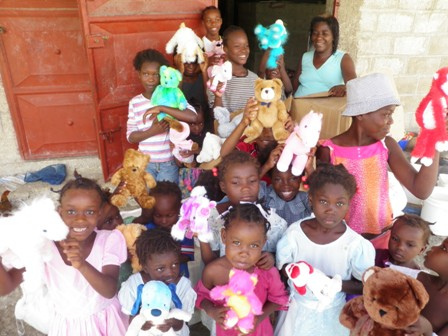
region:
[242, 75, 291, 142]
A light brown teddybear.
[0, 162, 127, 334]
A little girl wearing pink.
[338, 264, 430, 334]
A dark brown teddy bear.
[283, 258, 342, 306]
A red and white stuffed animal.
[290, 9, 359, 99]
A woman smiling wearing a blue shirt.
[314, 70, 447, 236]
A girl wearing a hat.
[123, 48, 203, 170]
A little girl wearing a striped shirt.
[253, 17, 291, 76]
A blue stuffed animal.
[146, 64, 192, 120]
A green stuffed animal.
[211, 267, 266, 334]
A pink stuffed animal.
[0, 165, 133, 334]
young girl in a pink dress holding up a stuffed unicorn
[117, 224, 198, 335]
young girl holding a blue and white stuffed animal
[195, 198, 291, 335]
girl in a dark pink dress holding a pink stuffed animal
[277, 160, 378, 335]
girl in a light blue dress holding a white and red stuffed animal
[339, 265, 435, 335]
stuffed brown teddy bear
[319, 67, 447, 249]
girl looking at her red and white stuffed animal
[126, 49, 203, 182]
girl hugging multicolored stuffed bear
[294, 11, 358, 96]
woman wearing a light blue tank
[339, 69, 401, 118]
hat on a young girl's head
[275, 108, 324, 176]
stuffed pink unicorn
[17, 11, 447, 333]
a group of children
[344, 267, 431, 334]
a brown bear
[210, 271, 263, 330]
a pink and yellow bear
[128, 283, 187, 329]
a blue and white dog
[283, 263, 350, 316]
a red and white dog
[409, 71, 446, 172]
a red and white monkey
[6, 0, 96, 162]
a orange door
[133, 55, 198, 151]
a girl holding a green bear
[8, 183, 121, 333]
a girl holding a white horse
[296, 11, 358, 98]
a woman in a mint green top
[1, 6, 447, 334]
a group of children posing with stuffed toys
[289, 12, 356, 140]
woman with her hand on a box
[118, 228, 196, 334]
small girl holding a blue and white stuffed dog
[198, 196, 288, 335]
girl holding a pink and yellow stuffed bear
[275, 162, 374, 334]
girl holding a white stuffed dog with dark pink ears, nose, and eyes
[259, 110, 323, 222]
girl holding a stuffed horse above her head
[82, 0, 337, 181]
an open red door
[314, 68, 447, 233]
girl holding up a toy monkey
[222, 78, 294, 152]
child holding up a teddy bear with a bow around its neck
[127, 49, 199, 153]
girl hugging a blue-green bear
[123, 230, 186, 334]
little girl with a blue dog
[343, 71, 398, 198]
little girl with pink shirt and beige hat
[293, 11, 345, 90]
woman in blue tank top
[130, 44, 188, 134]
girl hugging blue yellow and green bear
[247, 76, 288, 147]
kid with a brown teddy bear on his head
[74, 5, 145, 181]
red door behind the children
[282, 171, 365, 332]
little girl in a white dress holding a red and white dog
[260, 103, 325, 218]
little girl holding up a white horse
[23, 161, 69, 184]
grungy blue bag on the floor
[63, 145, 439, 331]
group of children with stuffed animals